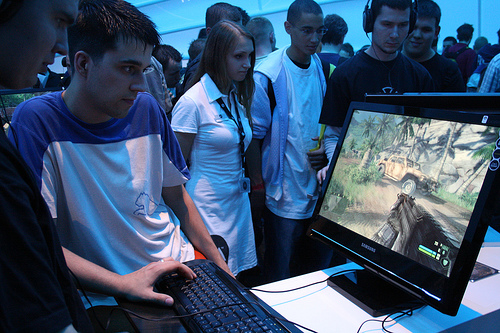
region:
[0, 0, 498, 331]
people watching people play video games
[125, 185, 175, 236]
puma logo on the shirt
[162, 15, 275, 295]
woman wearing a badge around her neck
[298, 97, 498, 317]
Computer screen with a video game on it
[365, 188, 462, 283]
player's weapon of choice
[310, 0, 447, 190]
man wearing headphones while playing the game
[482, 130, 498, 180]
stickers on the side of the computer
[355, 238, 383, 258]
samsung logo on the bottom of the computer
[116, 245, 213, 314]
man's hand pushing the keys on the keyboard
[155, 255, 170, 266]
man's gold banded wedding ring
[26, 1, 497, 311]
the guy in white t-shirt is looking in to the computer monitor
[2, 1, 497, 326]
the person in black dress is placing his finger in the keyboard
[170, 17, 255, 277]
a woman in white dress is standing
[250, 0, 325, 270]
the guy is wearing blue color jeans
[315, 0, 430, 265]
a guy in black dress is standing behind the computer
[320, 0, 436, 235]
the guy is wearing a head set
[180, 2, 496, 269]
a group of people are standing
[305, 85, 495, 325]
a monitor of desktop computer on the table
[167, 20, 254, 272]
the lady is wearing a tag around her neck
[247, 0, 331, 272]
the person is wearing red color band on his wrist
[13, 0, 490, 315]
crowd of people at an expo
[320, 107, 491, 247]
video game on computer screen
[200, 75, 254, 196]
woman with a black lanyard around her neck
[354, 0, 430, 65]
man wearing head phones on his head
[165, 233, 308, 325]
black computer keyboard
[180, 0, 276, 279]
woman wearing a jersey dress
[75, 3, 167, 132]
man with short brown hair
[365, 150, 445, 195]
jeep on the computer screen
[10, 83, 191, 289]
blue and white t-shirt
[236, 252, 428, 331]
black wires attached to monitor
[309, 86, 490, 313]
the screen is on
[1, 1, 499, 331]
they are playing a video game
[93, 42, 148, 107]
the boy is watching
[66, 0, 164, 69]
the boy has short hair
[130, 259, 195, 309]
the man has hands on the keyboard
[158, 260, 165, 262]
the man is wearing a ring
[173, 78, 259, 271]
the girl has a white dress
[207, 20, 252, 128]
the girl has long hair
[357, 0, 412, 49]
the boy has headphone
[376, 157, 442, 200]
an image of a car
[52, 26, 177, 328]
person watching computer monitor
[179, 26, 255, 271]
person watching computer monitor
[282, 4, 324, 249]
person watching computer monitor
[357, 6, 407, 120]
person watching computer monitor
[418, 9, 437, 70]
person watching computer monitor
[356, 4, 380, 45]
headphones on person's head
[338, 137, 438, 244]
fps on computer screen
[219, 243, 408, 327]
screen on white desk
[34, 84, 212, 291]
white and blue shirt on boy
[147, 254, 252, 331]
black keyboard on desk